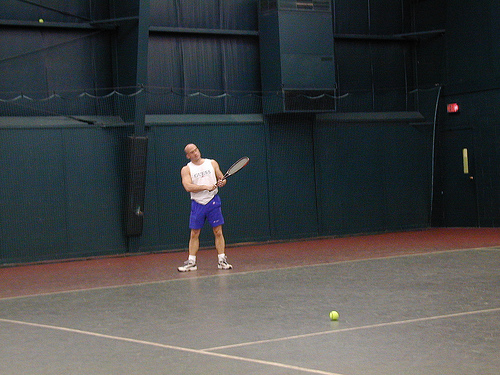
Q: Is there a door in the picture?
A: Yes, there is a door.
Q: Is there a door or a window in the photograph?
A: Yes, there is a door.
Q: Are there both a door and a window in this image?
A: Yes, there are both a door and a window.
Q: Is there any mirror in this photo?
A: No, there are no mirrors.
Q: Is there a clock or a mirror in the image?
A: No, there are no mirrors or clocks.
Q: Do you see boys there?
A: No, there are no boys.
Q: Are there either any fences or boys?
A: No, there are no boys or fences.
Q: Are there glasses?
A: No, there are no glasses.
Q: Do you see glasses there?
A: No, there are no glasses.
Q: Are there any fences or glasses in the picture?
A: No, there are no glasses or fences.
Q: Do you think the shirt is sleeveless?
A: Yes, the shirt is sleeveless.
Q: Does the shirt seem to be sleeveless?
A: Yes, the shirt is sleeveless.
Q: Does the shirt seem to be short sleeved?
A: No, the shirt is sleeveless.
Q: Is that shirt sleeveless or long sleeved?
A: The shirt is sleeveless.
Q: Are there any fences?
A: No, there are no fences.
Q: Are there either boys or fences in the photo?
A: No, there are no fences or boys.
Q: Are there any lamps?
A: No, there are no lamps.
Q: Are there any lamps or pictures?
A: No, there are no lamps or pictures.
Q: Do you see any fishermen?
A: No, there are no fishermen.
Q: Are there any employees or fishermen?
A: No, there are no fishermen or employees.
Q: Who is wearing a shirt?
A: The man is wearing a shirt.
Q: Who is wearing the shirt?
A: The man is wearing a shirt.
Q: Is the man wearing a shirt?
A: Yes, the man is wearing a shirt.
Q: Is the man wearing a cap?
A: No, the man is wearing a shirt.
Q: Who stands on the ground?
A: The man stands on the ground.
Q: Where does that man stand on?
A: The man stands on the ground.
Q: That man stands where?
A: The man stands on the ground.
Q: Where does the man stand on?
A: The man stands on the ground.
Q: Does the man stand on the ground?
A: Yes, the man stands on the ground.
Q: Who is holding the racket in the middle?
A: The man is holding the tennis racket.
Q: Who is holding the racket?
A: The man is holding the tennis racket.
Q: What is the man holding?
A: The man is holding the racket.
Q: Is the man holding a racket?
A: Yes, the man is holding a racket.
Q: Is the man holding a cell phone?
A: No, the man is holding a racket.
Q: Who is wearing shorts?
A: The man is wearing shorts.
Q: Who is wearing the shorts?
A: The man is wearing shorts.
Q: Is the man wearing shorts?
A: Yes, the man is wearing shorts.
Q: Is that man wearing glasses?
A: No, the man is wearing shorts.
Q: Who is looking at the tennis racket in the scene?
A: The man is looking at the tennis racket.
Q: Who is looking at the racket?
A: The man is looking at the tennis racket.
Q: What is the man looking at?
A: The man is looking at the tennis racket.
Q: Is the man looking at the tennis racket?
A: Yes, the man is looking at the tennis racket.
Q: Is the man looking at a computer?
A: No, the man is looking at the tennis racket.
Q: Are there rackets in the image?
A: Yes, there is a racket.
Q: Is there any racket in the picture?
A: Yes, there is a racket.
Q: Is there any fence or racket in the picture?
A: Yes, there is a racket.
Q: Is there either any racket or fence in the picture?
A: Yes, there is a racket.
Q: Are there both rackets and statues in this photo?
A: No, there is a racket but no statues.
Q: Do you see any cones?
A: No, there are no cones.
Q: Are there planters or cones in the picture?
A: No, there are no cones or planters.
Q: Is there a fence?
A: No, there are no fences.